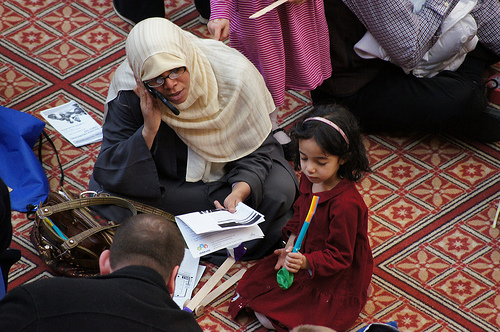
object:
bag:
[0, 106, 50, 212]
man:
[0, 213, 202, 332]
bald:
[135, 212, 162, 232]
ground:
[1, 0, 498, 330]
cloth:
[98, 17, 275, 183]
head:
[124, 18, 197, 106]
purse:
[27, 189, 139, 280]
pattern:
[411, 174, 464, 214]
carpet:
[0, 0, 500, 332]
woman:
[88, 16, 298, 265]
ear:
[168, 265, 179, 294]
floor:
[3, 0, 500, 324]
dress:
[229, 177, 373, 330]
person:
[85, 17, 299, 261]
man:
[330, 0, 498, 140]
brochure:
[38, 100, 106, 148]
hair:
[285, 105, 373, 182]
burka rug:
[13, 17, 100, 89]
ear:
[340, 155, 349, 165]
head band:
[303, 116, 349, 141]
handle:
[35, 184, 139, 250]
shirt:
[7, 262, 194, 330]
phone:
[144, 80, 181, 116]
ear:
[99, 250, 111, 275]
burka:
[93, 78, 302, 232]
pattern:
[7, 7, 108, 95]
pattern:
[429, 291, 487, 329]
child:
[229, 117, 372, 332]